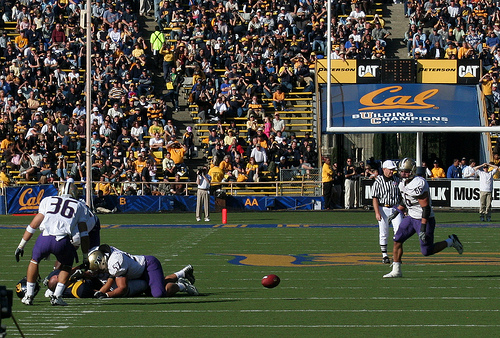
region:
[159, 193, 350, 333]
a football field is green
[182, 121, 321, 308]
a football field is green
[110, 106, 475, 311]
a football field is green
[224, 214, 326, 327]
a football field is green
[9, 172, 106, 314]
Football player with number 36 jersey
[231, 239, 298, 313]
Football on a green football field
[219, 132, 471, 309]
Football player in purple pants running towards a football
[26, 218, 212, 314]
Two football players on the ground one made a tackle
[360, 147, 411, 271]
Referee wearing black and white striped shirt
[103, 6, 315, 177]
Many people sitting in stands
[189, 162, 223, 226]
Man wearing tan pants and a white shirt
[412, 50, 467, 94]
Yellow sign that reads peterson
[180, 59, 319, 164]
People on yellow seats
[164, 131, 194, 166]
Man standing in yellow shirt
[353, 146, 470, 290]
player getting ready to kick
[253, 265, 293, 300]
football bouncing on the field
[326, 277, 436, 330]
white lines on the football field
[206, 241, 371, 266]
yellow and blue logo on the field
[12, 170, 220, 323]
football players tackling each other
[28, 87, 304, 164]
football fans in the bleachers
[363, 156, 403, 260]
referee for a football game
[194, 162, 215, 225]
man video taping the football game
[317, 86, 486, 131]
awning over the coaches area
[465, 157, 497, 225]
man watching the football game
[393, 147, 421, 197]
Person wearing football helmet.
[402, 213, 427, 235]
Person wearing blue pants.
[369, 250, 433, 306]
Person wearing white shoes.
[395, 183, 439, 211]
Person wearing white jersey.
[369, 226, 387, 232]
Ref wearing white pants.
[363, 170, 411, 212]
Ref wearing black and white striped shirt.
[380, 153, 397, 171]
Ref wearing white cap.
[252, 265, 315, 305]
Football on football field.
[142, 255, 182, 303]
Person wearing blue pants.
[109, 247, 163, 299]
Person wearing white jersey.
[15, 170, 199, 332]
Football players play football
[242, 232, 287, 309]
The football is laying on the ground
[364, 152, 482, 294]
A player and referee stand beside each other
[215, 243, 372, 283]
There is paint on the field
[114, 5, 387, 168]
A huge group of spectators watch the game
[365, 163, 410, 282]
The referee wears black and white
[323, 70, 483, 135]
The overhang is painted with a team name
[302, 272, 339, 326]
There are lines painted on the field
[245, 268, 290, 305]
The football is brown and white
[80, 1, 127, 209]
The metal pole is in the field